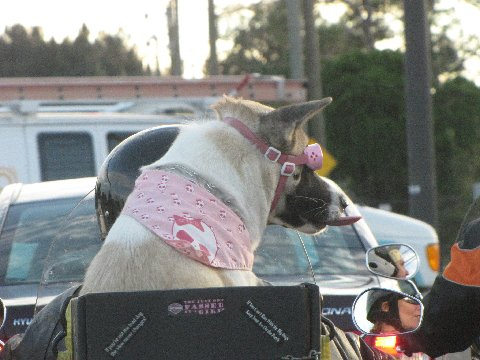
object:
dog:
[78, 93, 360, 360]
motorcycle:
[0, 281, 425, 360]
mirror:
[351, 287, 424, 337]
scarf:
[121, 170, 254, 269]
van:
[0, 74, 250, 195]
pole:
[405, 0, 437, 241]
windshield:
[32, 187, 319, 319]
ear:
[265, 96, 334, 126]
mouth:
[302, 206, 362, 235]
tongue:
[330, 216, 360, 225]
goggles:
[223, 116, 324, 223]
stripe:
[442, 243, 479, 287]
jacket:
[415, 218, 480, 358]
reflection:
[364, 288, 420, 334]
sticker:
[167, 298, 228, 315]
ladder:
[0, 73, 309, 103]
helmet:
[95, 123, 184, 242]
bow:
[173, 213, 204, 231]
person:
[0, 123, 400, 359]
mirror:
[365, 242, 419, 281]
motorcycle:
[364, 242, 480, 360]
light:
[375, 335, 396, 354]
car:
[0, 175, 403, 360]